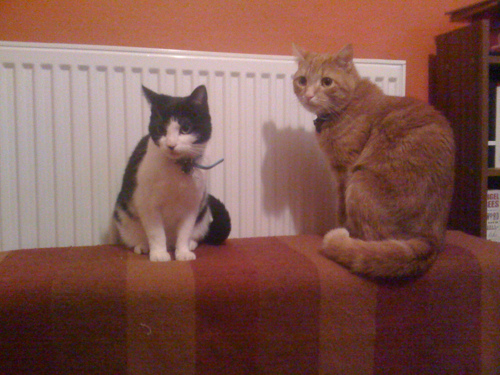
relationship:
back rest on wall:
[0, 40, 407, 253] [7, 8, 488, 330]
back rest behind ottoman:
[0, 40, 407, 253] [4, 178, 498, 368]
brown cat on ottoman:
[291, 42, 457, 279] [2, 224, 498, 371]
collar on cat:
[173, 151, 234, 177] [94, 79, 238, 266]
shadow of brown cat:
[262, 119, 334, 233] [291, 42, 457, 279]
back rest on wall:
[0, 40, 407, 253] [1, 0, 481, 104]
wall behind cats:
[1, 3, 500, 375] [92, 61, 469, 263]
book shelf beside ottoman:
[425, 0, 500, 246] [2, 224, 498, 371]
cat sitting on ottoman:
[113, 84, 230, 263] [2, 224, 498, 371]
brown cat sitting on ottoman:
[291, 42, 457, 279] [2, 224, 498, 371]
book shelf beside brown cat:
[425, 0, 500, 246] [291, 42, 457, 279]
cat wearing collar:
[96, 83, 252, 268] [166, 153, 227, 173]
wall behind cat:
[1, 3, 443, 182] [113, 84, 230, 263]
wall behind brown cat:
[1, 3, 443, 182] [291, 42, 457, 279]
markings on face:
[164, 110, 202, 146] [148, 100, 208, 163]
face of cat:
[148, 100, 208, 163] [80, 77, 275, 234]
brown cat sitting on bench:
[291, 42, 457, 279] [6, 226, 498, 373]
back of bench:
[4, 37, 416, 253] [10, 43, 425, 248]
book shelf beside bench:
[425, 12, 498, 245] [6, 226, 498, 373]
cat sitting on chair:
[113, 84, 230, 263] [10, 238, 488, 374]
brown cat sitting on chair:
[291, 42, 457, 279] [10, 238, 488, 374]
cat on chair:
[113, 84, 230, 263] [10, 238, 488, 374]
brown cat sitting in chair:
[285, 40, 460, 286] [10, 238, 488, 374]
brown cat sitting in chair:
[291, 42, 457, 279] [10, 238, 488, 374]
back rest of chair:
[5, 40, 404, 248] [6, 31, 498, 339]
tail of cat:
[304, 217, 445, 277] [279, 53, 476, 290]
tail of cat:
[202, 189, 239, 270] [86, 78, 216, 249]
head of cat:
[142, 85, 214, 165] [113, 84, 230, 263]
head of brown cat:
[287, 16, 415, 153] [291, 42, 457, 279]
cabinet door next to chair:
[436, 36, 489, 231] [10, 238, 488, 374]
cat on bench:
[113, 84, 230, 263] [6, 226, 498, 373]